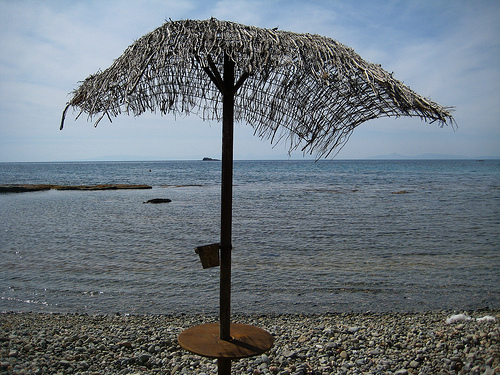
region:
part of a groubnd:
[313, 322, 368, 373]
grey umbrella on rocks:
[63, 16, 422, 135]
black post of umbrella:
[205, 100, 252, 350]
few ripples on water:
[320, 174, 405, 262]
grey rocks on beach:
[358, 324, 471, 371]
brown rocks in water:
[2, 173, 141, 213]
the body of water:
[0, 158, 497, 315]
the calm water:
[0, 159, 499, 316]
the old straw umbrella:
[59, 16, 459, 373]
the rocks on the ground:
[2, 308, 497, 374]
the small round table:
[177, 320, 274, 358]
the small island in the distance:
[202, 156, 219, 161]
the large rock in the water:
[140, 198, 172, 203]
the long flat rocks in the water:
[0, 182, 152, 192]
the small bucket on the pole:
[195, 242, 222, 269]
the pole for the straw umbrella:
[193, 50, 254, 373]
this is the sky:
[38, 31, 53, 48]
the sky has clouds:
[428, 50, 457, 83]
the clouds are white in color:
[443, 75, 468, 101]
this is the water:
[261, 176, 344, 283]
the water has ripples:
[283, 186, 356, 259]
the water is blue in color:
[278, 165, 303, 175]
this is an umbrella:
[139, 74, 279, 92]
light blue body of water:
[1, 163, 499, 311]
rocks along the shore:
[2, 313, 496, 371]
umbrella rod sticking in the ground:
[198, 124, 260, 371]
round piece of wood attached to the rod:
[172, 308, 282, 362]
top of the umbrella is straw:
[45, 10, 453, 166]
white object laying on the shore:
[443, 308, 497, 325]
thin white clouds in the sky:
[0, 0, 499, 160]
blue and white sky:
[0, 0, 499, 163]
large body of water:
[1, 160, 498, 307]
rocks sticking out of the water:
[1, 173, 156, 196]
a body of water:
[305, 145, 496, 313]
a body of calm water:
[311, 182, 487, 301]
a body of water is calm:
[286, 168, 467, 330]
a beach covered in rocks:
[356, 295, 446, 368]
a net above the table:
[140, 57, 340, 152]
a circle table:
[171, 291, 266, 370]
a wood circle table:
[161, 310, 281, 373]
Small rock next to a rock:
[260, 352, 272, 364]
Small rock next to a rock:
[337, 348, 347, 359]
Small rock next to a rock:
[405, 355, 423, 371]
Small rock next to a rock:
[482, 355, 496, 367]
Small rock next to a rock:
[322, 340, 337, 347]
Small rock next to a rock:
[139, 351, 151, 365]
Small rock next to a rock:
[58, 357, 70, 368]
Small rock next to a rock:
[6, 347, 16, 356]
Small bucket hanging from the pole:
[193, 240, 220, 268]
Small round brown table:
[180, 318, 274, 357]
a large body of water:
[0, 161, 499, 312]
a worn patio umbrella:
[58, 19, 454, 156]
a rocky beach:
[1, 312, 497, 373]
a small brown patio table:
[177, 320, 272, 358]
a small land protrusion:
[0, 182, 195, 194]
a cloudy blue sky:
[0, 0, 499, 159]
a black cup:
[195, 242, 221, 269]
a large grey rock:
[438, 356, 450, 363]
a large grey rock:
[280, 349, 295, 358]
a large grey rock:
[137, 353, 151, 364]